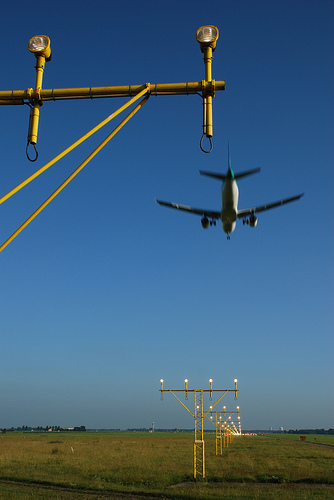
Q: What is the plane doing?
A: Getting ready to land.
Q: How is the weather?
A: Clear.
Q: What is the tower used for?
A: To help the plane land.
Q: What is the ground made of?
A: Grass.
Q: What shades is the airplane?
A: Green and White.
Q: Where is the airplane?
A: In the sky.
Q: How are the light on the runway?
A: Turned off.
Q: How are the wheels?
A: Wheels are down.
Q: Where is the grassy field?
A: At the airport.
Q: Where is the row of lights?
A: In the airport.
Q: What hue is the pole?
A: Yellow.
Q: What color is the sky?
A: Blue.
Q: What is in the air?
A: Airplane.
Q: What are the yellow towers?
A: Landing markers.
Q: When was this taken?
A: Daytime.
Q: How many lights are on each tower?
A: 4.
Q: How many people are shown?
A: 0.